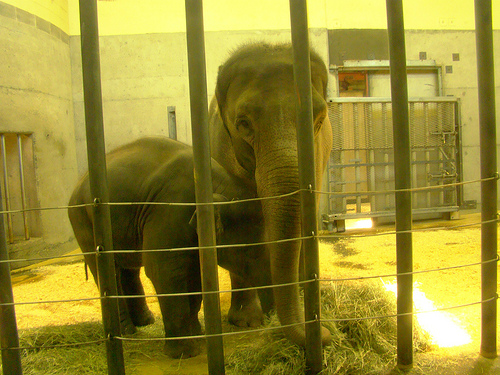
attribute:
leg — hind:
[119, 269, 151, 326]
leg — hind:
[81, 259, 137, 334]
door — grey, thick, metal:
[328, 61, 447, 226]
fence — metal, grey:
[350, 94, 454, 222]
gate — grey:
[319, 98, 481, 231]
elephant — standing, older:
[204, 42, 332, 347]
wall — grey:
[0, 0, 79, 272]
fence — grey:
[337, 85, 472, 194]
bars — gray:
[323, 88, 466, 228]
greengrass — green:
[282, 272, 494, 374]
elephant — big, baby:
[34, 68, 410, 334]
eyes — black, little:
[227, 104, 337, 151]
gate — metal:
[317, 84, 464, 234]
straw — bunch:
[27, 242, 434, 372]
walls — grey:
[97, 32, 192, 152]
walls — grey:
[70, 34, 91, 184]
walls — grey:
[204, 28, 331, 114]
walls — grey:
[402, 28, 482, 214]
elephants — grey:
[43, 28, 425, 370]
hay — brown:
[336, 292, 388, 366]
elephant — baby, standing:
[69, 133, 273, 356]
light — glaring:
[368, 285, 478, 356]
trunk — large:
[253, 141, 322, 367]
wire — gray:
[6, 182, 498, 351]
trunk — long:
[255, 124, 324, 347]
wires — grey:
[0, 170, 499, 361]